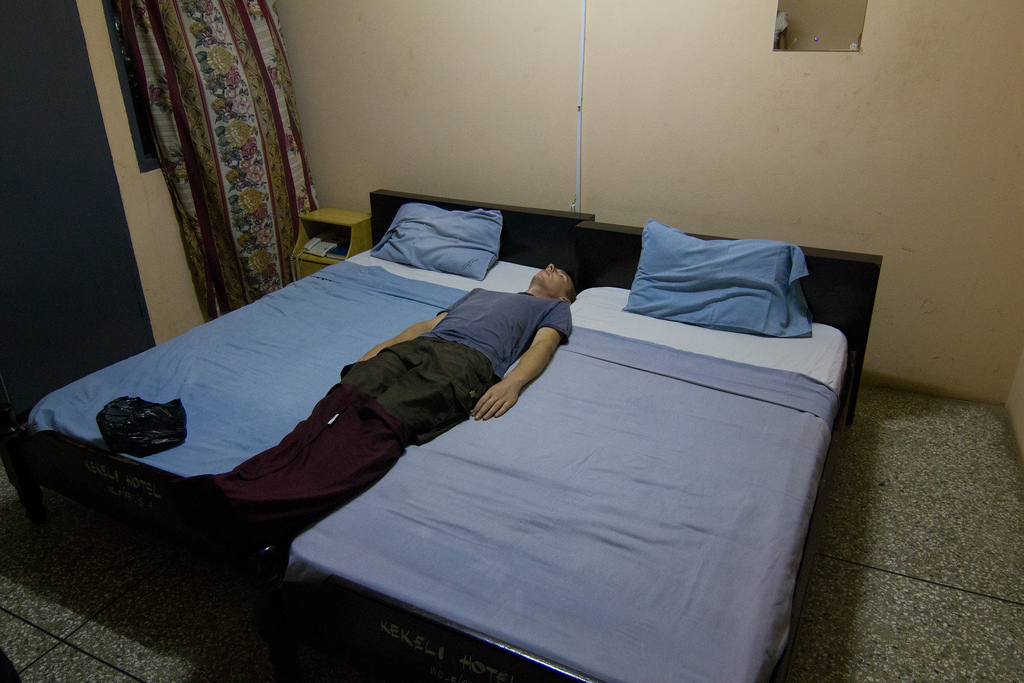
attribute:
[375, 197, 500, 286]
pillow — blue 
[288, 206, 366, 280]
table — brown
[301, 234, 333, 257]
phone — white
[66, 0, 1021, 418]
wall — painted, pink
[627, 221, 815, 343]
pillow — blue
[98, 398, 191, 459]
bag — black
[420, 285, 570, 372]
shirt — blue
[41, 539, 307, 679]
tile — big, ugly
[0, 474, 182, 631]
tile — big, ugly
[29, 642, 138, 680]
tile — big, ugly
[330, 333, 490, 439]
pants — green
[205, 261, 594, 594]
man — laying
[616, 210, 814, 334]
pillowcase — blue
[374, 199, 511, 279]
pillowcase — blue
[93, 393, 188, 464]
bag — black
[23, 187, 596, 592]
bed — plastic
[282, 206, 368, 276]
night stand — yellowish tan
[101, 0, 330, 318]
curtains — long, floral print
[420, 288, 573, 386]
shirt — blue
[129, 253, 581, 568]
man — laying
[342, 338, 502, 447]
khaki's — green 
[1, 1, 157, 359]
door — dark gray